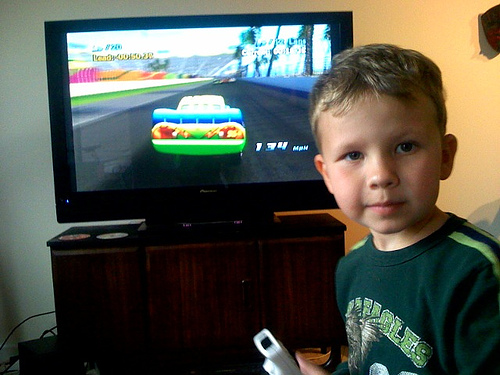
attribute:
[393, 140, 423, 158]
eye — blue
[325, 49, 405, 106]
hair — blonde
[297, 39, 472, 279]
boy — little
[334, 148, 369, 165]
eye — blue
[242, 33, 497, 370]
boy — little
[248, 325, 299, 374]
remote — white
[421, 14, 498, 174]
wall — small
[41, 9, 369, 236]
tv — flat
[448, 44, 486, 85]
wire — black